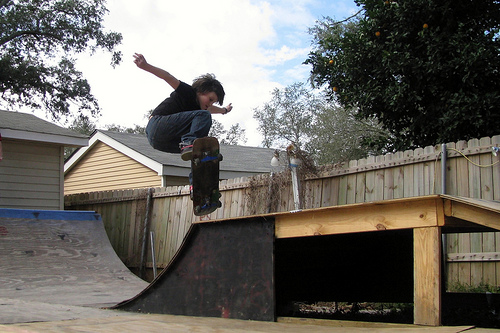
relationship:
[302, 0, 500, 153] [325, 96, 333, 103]
fruit tree has leaf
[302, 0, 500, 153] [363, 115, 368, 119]
fruit tree has leaf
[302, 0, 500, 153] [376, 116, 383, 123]
fruit tree has leaf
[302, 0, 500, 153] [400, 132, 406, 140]
fruit tree has leaf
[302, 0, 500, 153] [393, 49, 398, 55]
fruit tree has leaf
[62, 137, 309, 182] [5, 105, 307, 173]
roofs has shingles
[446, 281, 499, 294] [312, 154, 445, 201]
weeds along fence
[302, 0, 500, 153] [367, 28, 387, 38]
fruit tree has fruit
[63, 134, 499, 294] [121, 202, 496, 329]
fence behind ramp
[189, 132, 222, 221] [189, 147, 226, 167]
board has wheels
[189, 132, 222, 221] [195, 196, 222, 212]
board has wheels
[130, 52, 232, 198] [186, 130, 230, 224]
boy on skateboard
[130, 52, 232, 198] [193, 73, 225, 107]
boy has hair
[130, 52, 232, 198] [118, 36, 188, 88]
boy has arm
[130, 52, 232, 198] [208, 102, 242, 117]
boy has arm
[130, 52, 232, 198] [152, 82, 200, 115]
boy wear shirt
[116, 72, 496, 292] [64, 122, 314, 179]
building has roof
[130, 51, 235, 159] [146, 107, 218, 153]
boy wearing jeans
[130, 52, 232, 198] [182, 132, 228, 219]
boy on skateboard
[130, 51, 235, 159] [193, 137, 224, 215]
boy on board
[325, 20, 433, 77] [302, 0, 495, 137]
fruit on fruit tree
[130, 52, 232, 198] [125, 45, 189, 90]
boy has an arm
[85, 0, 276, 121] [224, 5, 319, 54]
cloud in sky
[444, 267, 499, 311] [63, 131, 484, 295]
weeds in front of fence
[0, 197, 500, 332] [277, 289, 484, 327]
ramp in yard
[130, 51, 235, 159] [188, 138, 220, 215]
boy riding skateboard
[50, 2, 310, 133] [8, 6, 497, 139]
cloud in sky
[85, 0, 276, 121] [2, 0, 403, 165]
cloud in sky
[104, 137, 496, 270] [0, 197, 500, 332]
fence behind ramp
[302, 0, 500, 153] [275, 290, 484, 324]
fruit tree in yard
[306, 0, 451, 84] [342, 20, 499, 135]
oranges on tree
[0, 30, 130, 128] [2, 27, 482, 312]
tree in yard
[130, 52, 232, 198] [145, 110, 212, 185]
boy wearing jeans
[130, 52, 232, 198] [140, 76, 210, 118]
boy wearing shirt